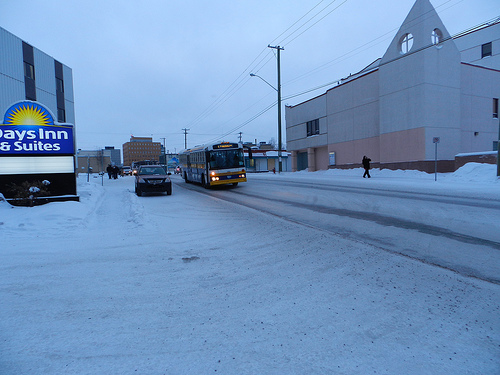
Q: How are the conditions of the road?
A: Snow covered.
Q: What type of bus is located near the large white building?
A: School bus.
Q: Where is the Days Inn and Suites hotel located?
A: On side of road.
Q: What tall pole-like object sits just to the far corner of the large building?
A: Street light.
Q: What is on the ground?
A: Snow.